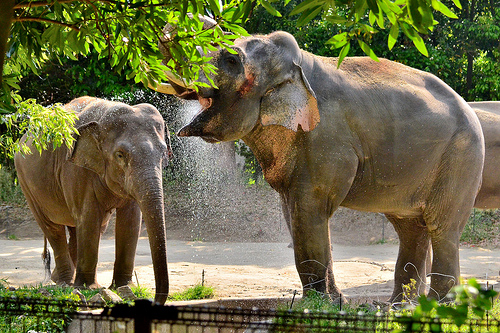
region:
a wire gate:
[4, 290, 491, 330]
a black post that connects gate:
[109, 299, 169, 331]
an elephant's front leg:
[291, 198, 345, 301]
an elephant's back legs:
[393, 220, 463, 296]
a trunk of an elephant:
[138, 171, 168, 303]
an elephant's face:
[201, 31, 313, 148]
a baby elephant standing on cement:
[14, 100, 203, 302]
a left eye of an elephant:
[105, 140, 135, 165]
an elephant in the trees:
[176, 22, 479, 297]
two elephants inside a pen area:
[13, 23, 488, 285]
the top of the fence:
[11, 287, 485, 327]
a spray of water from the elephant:
[168, 11, 229, 187]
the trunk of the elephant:
[150, 198, 161, 300]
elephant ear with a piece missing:
[252, 70, 337, 140]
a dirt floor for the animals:
[190, 254, 263, 276]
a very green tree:
[0, 6, 183, 69]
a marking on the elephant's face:
[231, 65, 262, 113]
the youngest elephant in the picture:
[0, 100, 180, 266]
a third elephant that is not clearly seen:
[469, 94, 496, 225]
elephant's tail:
[35, 232, 50, 269]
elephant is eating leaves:
[158, 11, 489, 329]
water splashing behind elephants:
[147, 34, 302, 259]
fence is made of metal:
[5, 289, 498, 331]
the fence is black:
[4, 291, 456, 330]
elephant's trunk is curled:
[149, 10, 240, 101]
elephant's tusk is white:
[115, 31, 195, 107]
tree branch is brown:
[0, 2, 65, 79]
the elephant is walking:
[4, 83, 220, 293]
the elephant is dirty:
[181, 24, 493, 265]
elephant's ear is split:
[289, 116, 306, 136]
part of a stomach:
[379, 113, 417, 174]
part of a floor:
[197, 235, 250, 275]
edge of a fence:
[197, 285, 235, 318]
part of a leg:
[293, 215, 325, 262]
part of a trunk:
[128, 166, 168, 216]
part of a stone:
[181, 138, 224, 194]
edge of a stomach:
[347, 172, 408, 235]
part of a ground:
[224, 262, 250, 290]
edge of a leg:
[318, 225, 338, 262]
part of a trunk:
[142, 217, 176, 264]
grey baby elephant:
[11, 89, 191, 309]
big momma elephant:
[139, 10, 491, 310]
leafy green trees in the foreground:
[0, 1, 454, 159]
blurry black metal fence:
[4, 290, 490, 331]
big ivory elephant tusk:
[127, 53, 178, 100]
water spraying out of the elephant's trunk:
[114, 76, 258, 225]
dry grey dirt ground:
[0, 229, 499, 301]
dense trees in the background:
[235, 4, 498, 106]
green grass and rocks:
[2, 279, 212, 331]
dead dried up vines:
[293, 254, 462, 307]